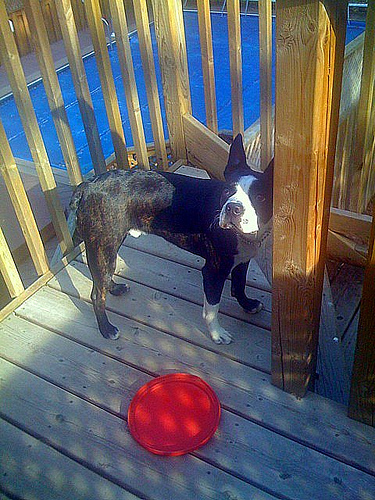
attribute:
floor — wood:
[1, 161, 373, 497]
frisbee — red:
[113, 365, 238, 465]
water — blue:
[1, 17, 363, 185]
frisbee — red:
[122, 366, 227, 462]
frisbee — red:
[115, 362, 226, 462]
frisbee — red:
[126, 371, 221, 456]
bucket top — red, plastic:
[125, 367, 219, 455]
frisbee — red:
[118, 354, 233, 470]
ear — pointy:
[221, 135, 254, 181]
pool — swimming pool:
[0, 4, 371, 186]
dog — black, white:
[64, 130, 273, 349]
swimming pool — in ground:
[0, 5, 274, 192]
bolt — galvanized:
[331, 331, 340, 342]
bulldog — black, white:
[64, 133, 280, 343]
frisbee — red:
[122, 367, 225, 453]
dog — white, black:
[69, 139, 284, 355]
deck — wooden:
[21, 104, 356, 498]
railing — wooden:
[0, 1, 372, 425]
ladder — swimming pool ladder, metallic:
[100, 15, 114, 49]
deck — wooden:
[0, 0, 373, 498]